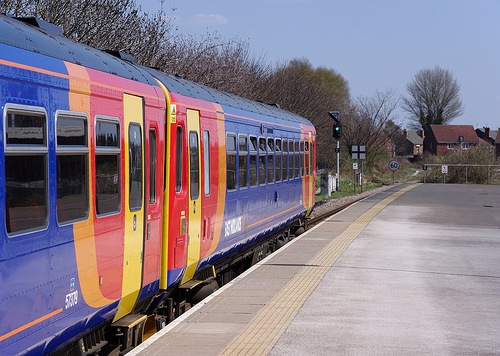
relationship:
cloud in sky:
[155, 12, 228, 27] [289, 14, 409, 38]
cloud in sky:
[155, 12, 228, 27] [324, 2, 414, 69]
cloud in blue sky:
[155, 12, 228, 27] [118, 0, 499, 133]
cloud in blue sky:
[155, 12, 228, 27] [0, 0, 499, 135]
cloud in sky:
[155, 12, 228, 27] [218, 10, 473, 53]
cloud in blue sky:
[155, 11, 179, 26] [118, 0, 499, 133]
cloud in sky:
[155, 12, 228, 27] [250, 11, 488, 73]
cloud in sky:
[155, 12, 228, 27] [256, 11, 392, 48]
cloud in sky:
[155, 12, 228, 27] [297, 17, 355, 41]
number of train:
[60, 287, 87, 314] [9, 26, 395, 338]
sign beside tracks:
[386, 159, 399, 172] [304, 193, 371, 223]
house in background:
[399, 118, 431, 160] [246, 27, 496, 266]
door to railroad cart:
[117, 86, 165, 321] [7, 125, 439, 354]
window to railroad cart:
[223, 132, 240, 192] [160, 70, 318, 288]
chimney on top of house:
[392, 116, 424, 148] [414, 100, 489, 180]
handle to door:
[146, 222, 150, 237] [141, 104, 166, 288]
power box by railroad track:
[328, 120, 348, 180] [144, 156, 413, 336]